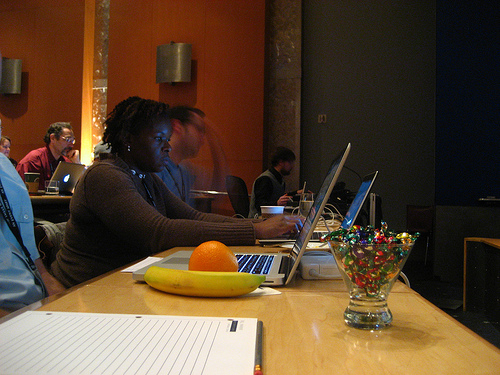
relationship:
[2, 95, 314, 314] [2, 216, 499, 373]
people are sitting at table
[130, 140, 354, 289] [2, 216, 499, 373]
computers on table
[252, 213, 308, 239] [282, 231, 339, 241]
hands are on keyboard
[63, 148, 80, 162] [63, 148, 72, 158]
hand on chin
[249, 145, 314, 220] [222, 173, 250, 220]
man sitting in chair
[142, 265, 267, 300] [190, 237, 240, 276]
banana sitting beside orange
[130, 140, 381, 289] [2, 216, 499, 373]
computers are on table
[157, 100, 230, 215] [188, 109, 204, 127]
man rubbing h head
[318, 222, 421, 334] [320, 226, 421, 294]
glass full of candy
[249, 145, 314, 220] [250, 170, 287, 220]
man wearing a vest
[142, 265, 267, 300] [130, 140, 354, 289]
banana next to computers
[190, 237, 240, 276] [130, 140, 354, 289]
orange next to computers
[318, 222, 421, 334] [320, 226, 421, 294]
dish full of candy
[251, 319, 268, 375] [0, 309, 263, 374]
pencil above paper